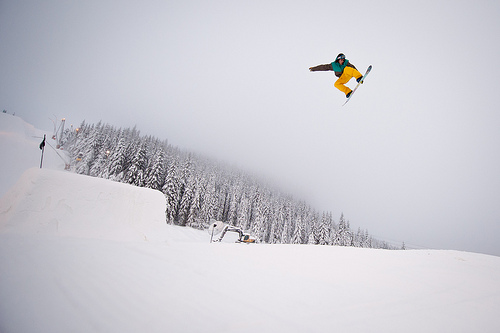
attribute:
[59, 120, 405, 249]
trees — large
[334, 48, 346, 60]
hat — black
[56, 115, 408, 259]
trees — snow covered, large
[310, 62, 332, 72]
arm — extended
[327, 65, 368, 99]
pants — yellow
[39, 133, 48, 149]
black flag — on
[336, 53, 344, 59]
goggles — white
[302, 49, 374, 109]
man — riding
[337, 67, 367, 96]
pants — yellow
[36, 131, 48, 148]
flag — black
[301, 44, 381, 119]
man — off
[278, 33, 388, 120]
person — yellow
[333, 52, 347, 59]
helmet —  blue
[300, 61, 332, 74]
arm — on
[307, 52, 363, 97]
man — snowboarding, grabbing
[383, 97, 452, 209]
sky — gray, foggy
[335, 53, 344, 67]
head — of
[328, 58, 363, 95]
jacket — brown, blue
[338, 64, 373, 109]
board — black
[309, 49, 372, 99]
skies — on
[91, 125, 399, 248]
trees — behind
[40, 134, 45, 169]
post — metal